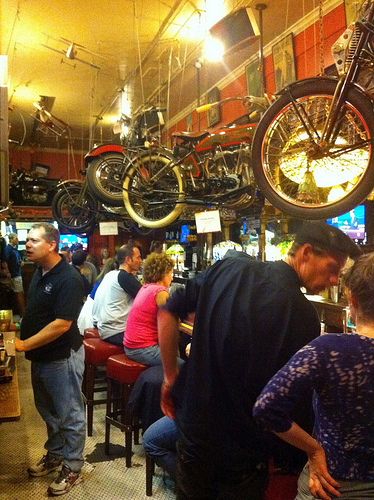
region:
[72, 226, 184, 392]
several people sitting at a bar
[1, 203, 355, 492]
several people in a bar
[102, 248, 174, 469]
a woman sitting on a bar stool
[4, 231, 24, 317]
a man holding a beer in a bar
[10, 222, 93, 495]
a man standing at a bar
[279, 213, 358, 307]
a man wearing a cap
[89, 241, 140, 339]
a man wearing a white and blue shirt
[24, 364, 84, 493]
the legs of a man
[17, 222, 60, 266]
the head of a man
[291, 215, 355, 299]
the head of a man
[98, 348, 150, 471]
red leather seat stool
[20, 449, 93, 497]
pair of grey sneakers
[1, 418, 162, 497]
patch of small off white tiled flooring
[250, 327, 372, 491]
purple lace half quarter sleeve shirt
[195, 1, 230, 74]
lights on ceiling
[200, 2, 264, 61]
silver and black speaker suspended from the roof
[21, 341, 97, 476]
pair of blue jeans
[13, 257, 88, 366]
black short sleeve collard shirt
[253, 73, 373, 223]
black front tire of motorcycle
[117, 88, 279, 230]
silver and white bicycle suspended from ceiling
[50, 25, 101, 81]
model airplane on the ceiling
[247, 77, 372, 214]
black tire on motor bike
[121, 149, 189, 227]
back tire on motor bike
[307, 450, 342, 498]
the woman's left hand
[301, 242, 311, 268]
the man's right ear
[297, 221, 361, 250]
hat on the man's head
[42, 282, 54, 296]
logo on the man's shirt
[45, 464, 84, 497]
left shoe on man's foot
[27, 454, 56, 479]
right foot on man's shoe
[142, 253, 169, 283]
the woman's frizzy hair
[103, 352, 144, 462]
part of a red stool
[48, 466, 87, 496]
a man's tennis shoe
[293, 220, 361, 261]
a black hat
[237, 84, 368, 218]
the wheel of a bike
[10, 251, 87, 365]
a man's black shirt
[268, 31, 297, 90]
a picture frame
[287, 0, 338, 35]
part of a white wall trim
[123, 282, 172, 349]
a woman's pink tank top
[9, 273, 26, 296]
a man's shorts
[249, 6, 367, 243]
small motorcycle hanging from ceiling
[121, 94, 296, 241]
small motorcycle hanging from ceiling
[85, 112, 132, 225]
small motorcycle hanging from ceiling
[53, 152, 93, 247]
small motorcycle hanging from ceiling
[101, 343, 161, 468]
red stool at bar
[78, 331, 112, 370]
red stool at bar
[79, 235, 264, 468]
people sitting at bar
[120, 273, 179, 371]
woman with a pink shirt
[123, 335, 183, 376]
woman wearing blue jeans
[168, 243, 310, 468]
man wearing a black shirt